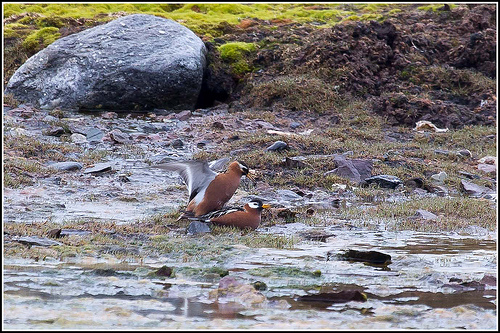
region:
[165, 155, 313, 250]
two birds on the ground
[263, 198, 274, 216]
beak of the bird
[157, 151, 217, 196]
feather of the bird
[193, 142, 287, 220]
one bird on top of the other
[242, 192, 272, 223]
black and white bird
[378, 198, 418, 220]
green grass on the ground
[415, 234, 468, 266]
water on the ground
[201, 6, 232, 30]
green grass in background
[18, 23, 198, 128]
rock on the ground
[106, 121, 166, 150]
rocks below the other rocks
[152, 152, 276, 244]
TWO BIRDS TOGETHER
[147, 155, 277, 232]
THESE ARE BIRDS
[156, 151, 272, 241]
THE BIRD'S BODIES ARE RED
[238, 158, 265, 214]
THE BIRDS HAVE BLACK AND WHITE FACES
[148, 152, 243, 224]
THE BIRDS HAVE BLACK AND WHITE WINGS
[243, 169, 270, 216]
THE BIRDS HAVE YELLOW BEAKS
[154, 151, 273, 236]
THE BIRDS ARE ON THE BEACH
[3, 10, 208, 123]
THE BOULDER IS BIG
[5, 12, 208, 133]
THIS IS A BOULDER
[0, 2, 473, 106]
THE MOSS IS BRIGHT GREEN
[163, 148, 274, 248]
two birds mating in the wild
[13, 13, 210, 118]
gray rock with white spots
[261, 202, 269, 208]
bright orange beak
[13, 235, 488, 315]
muddy pond water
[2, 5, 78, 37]
short green moss growing on rocks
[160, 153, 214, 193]
gray bird wing flapping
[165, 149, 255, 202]
brown, black, and white bird flapping its wings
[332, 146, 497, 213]
sharp rocks in the grass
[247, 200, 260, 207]
black and white bird's eye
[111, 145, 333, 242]
two brown and white birds sitting in a swamp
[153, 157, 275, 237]
two birds sitting on the ground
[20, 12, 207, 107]
a big greyish rock sitting by the grass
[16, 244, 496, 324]
running water by the birds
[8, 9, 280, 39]
bright green mossy grass by the rock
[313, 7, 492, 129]
a mound of dirt next to the grass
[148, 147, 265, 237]
the bird that is stretching its wings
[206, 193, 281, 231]
the bird that is laying down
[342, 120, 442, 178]
some dried up grass around the stones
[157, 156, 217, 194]
the wing of the standing birdi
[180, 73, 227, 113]
a shadow by the rock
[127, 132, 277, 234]
Two birds sitting on land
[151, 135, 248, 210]
Birds wings are outstretched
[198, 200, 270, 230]
Bird is crouched on the ground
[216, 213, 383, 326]
The water is full of gunk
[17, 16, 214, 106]
Huge boulder on the land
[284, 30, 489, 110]
Pile of dirt on hill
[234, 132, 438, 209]
Group of rocks on the shore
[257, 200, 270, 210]
The bird has an orange beak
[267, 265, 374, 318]
The water is not clear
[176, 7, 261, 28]
Moss on the hill